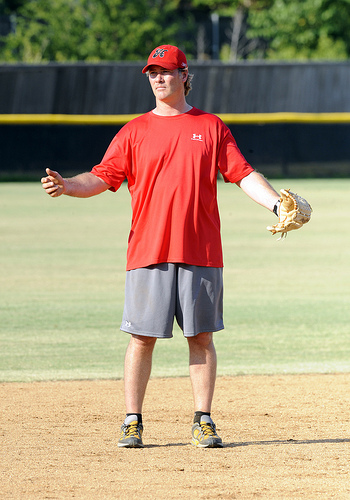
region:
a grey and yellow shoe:
[120, 413, 144, 448]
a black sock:
[125, 409, 145, 421]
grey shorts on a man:
[118, 263, 227, 341]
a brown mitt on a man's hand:
[270, 189, 315, 231]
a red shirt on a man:
[92, 102, 255, 271]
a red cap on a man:
[141, 43, 186, 72]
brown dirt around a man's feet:
[2, 373, 348, 498]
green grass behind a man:
[0, 176, 348, 381]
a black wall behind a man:
[1, 58, 348, 182]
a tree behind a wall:
[230, 4, 348, 56]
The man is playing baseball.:
[41, 43, 309, 448]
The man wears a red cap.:
[140, 43, 187, 72]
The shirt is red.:
[140, 176, 207, 258]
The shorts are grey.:
[128, 280, 165, 329]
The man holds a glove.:
[262, 186, 313, 235]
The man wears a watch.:
[271, 196, 282, 215]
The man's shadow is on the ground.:
[221, 438, 348, 447]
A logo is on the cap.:
[151, 46, 168, 58]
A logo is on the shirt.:
[191, 132, 203, 141]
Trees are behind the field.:
[1, 1, 140, 61]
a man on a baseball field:
[40, 21, 344, 489]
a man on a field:
[75, 16, 236, 319]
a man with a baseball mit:
[83, 37, 333, 371]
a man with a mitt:
[61, 83, 347, 283]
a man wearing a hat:
[106, 48, 305, 193]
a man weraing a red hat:
[127, 28, 188, 134]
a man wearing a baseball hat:
[118, 11, 220, 126]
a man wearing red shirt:
[107, 52, 279, 301]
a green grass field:
[67, 256, 342, 396]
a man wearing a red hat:
[138, 38, 201, 88]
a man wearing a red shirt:
[131, 104, 228, 252]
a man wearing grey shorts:
[106, 252, 224, 350]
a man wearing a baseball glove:
[264, 183, 310, 238]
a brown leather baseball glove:
[261, 153, 324, 237]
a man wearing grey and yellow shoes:
[116, 405, 151, 458]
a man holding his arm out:
[24, 107, 150, 223]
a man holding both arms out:
[26, 123, 320, 243]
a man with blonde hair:
[175, 48, 194, 104]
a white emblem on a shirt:
[181, 120, 208, 153]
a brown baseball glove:
[266, 190, 317, 235]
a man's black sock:
[191, 408, 208, 423]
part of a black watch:
[274, 200, 282, 217]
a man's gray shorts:
[121, 259, 228, 343]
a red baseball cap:
[141, 41, 192, 77]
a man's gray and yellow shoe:
[192, 413, 226, 449]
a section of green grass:
[1, 182, 144, 380]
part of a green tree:
[245, 3, 348, 61]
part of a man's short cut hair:
[182, 73, 195, 95]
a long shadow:
[227, 433, 349, 449]